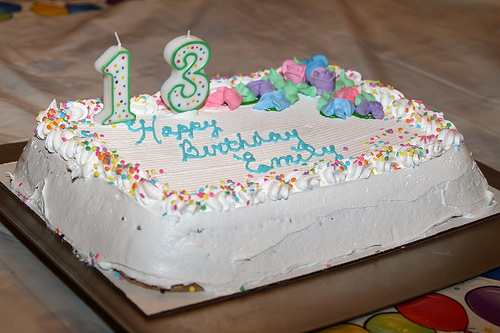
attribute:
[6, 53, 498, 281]
cake — colorful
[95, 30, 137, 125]
1 — candle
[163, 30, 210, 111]
3 — candle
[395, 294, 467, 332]
balloon — red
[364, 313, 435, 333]
balloon — yellow